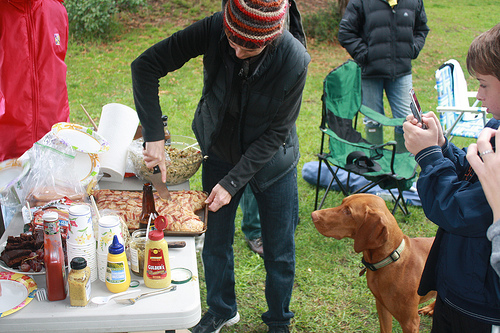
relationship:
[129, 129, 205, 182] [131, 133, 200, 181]
glass has pasta salad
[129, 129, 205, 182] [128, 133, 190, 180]
glass has pasta salad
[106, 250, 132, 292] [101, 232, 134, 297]
yellow mustard in bottle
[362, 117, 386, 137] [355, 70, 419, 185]
knee in pants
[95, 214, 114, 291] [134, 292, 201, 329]
paper cups on table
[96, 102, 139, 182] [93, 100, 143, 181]
paper towels wrapped around roll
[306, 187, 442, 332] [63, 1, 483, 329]
dog standing in grass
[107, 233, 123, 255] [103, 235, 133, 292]
lid covering bottle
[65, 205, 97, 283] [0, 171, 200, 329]
cup stacked on table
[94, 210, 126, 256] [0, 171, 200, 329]
cup stacked on table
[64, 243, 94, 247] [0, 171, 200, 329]
cup stacked on table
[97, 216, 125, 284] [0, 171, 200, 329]
cup stacked on table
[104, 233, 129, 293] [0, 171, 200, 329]
mustard sitting on table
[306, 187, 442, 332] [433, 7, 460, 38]
dog standing on grass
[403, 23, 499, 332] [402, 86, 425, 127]
boy holding cell phone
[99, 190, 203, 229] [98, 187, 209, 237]
pizza sitting on metal tray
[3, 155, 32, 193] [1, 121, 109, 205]
plate lying in pile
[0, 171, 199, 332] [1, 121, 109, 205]
plate lying in pile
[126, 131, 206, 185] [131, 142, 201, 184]
bowl containing salad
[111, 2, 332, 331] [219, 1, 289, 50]
person wearing cap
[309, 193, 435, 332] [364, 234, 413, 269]
dog wearing collar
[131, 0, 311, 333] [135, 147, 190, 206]
person using knife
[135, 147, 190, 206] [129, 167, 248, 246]
knife to cut food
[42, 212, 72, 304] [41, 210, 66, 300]
bottle of ketchup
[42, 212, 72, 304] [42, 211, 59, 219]
bottle with lid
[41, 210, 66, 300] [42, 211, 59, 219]
ketchup with lid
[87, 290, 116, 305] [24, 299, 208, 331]
plastic spoon on table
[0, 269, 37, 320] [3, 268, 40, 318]
paper plate with rim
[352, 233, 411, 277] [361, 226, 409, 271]
collar on neck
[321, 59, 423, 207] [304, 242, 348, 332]
chair on grass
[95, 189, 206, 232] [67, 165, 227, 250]
pizza inside pan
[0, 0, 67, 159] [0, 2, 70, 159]
person wearing jacket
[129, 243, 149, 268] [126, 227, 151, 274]
pickles in jar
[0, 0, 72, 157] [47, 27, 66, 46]
red jacket with white logo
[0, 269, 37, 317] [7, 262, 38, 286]
paper plate with border